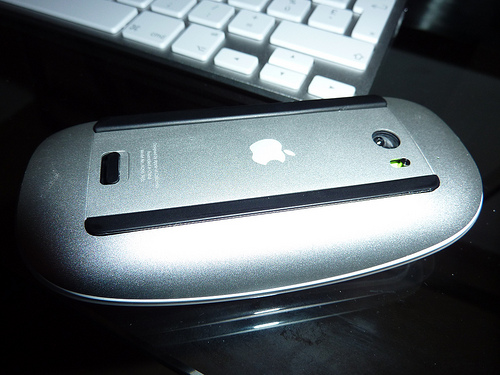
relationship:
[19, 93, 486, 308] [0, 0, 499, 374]
mouse on table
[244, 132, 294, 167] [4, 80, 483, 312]
apple on mouse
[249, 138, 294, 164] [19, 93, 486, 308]
apple on mouse